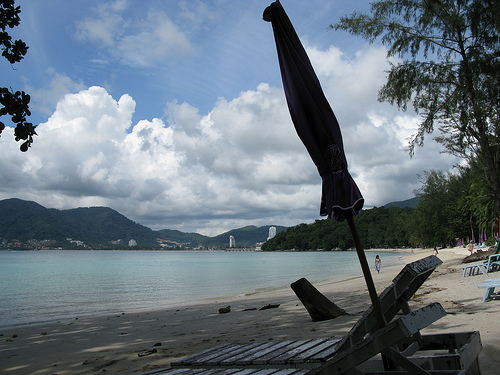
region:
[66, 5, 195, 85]
this is the sky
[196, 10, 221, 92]
the sky is blue in color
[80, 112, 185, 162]
this is the cloud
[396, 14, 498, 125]
this is a tree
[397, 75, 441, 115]
the leaves are greenin color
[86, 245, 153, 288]
this is a water body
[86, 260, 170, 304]
the water is calm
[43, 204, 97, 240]
this is a hill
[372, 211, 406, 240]
this is a forest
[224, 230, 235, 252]
this is a building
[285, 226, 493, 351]
a chair on a beach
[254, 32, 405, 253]
a umbrella on a beach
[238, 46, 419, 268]
a tall umbrella on a beach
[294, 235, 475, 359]
a wood chair on a beach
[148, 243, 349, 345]
sand on a beach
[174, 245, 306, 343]
lots of sand on a beach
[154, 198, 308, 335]
sand near water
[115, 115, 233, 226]
clouds in the sky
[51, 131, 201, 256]
mountains in the background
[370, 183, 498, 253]
green leaves on a tree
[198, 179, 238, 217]
part of a cloud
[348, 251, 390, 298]
part of a handle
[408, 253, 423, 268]
part of a handle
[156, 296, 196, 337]
part of a handke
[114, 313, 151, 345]
par tof a sand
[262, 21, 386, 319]
umbrella is in sand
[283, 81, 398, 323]
umbrella in sand is folded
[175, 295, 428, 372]
wooden chair near umbrella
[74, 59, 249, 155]
blue and white sky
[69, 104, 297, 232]
puffy white clouds in sky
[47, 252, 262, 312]
water is light blue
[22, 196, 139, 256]
green trees on mountain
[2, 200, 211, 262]
large mountain in distance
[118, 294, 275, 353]
sand is light brown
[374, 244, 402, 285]
woman walking near water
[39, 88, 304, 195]
white clouds in the sky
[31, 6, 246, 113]
the blue part of the sky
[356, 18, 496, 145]
a tree on the beach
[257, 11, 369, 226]
a closed umbrella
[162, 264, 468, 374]
a wooden beach chair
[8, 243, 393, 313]
the ocean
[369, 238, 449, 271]
people standing on the beach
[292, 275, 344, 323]
the stump of a tree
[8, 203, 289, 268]
mountains surrounding the ocean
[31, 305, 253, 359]
sand on the beach